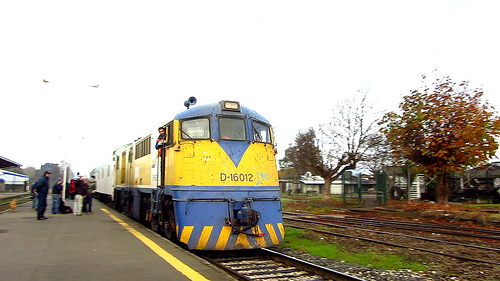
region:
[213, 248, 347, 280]
train tracks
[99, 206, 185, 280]
a yellow warning strip on a train platform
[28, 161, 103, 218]
people standing on a train platform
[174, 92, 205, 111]
a horn on a train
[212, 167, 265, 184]
identification numbers on a train engine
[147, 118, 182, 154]
a man leaning out the window of a train engine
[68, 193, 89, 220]
white pants worn by a man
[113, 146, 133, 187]
a door to a train car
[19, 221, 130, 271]
a cement platform at a train station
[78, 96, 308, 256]
a train parked at a train station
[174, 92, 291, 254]
front of train is yellow and blue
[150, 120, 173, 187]
a person on door of train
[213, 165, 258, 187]
number of train is D-16012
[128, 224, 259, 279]
a yellow line on side railroad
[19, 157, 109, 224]
group of people on a platform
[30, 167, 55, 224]
person wears blue cloths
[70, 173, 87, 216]
person wears white pants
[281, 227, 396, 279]
patch of grass near railroad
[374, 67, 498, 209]
a tree with dry leaves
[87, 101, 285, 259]
large blue and yellow train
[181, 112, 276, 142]
small windshield in front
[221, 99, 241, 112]
small front light in the top of train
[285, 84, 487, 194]
autumn trees in the right side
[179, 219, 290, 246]
yellow lines of blue train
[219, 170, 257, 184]
black letters in the front of train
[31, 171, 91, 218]
people standing on platform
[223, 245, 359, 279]
black rusty train tracks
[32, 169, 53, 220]
man wearing blue jacket on platform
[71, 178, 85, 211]
man wearing white pants standing on the platform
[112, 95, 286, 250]
blue and yellow train locomotive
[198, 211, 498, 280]
sets of train tracks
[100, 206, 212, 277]
yellow caution stripe painted on platform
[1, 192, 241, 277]
train station platform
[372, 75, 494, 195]
tree with leaves turning yellow and red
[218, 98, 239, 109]
train headlight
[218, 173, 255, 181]
locomotive identifying number D-16012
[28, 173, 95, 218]
people waiting on open air train platform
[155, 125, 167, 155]
train engineer in orange vest leaning out engine side window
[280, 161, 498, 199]
houses near the train tracks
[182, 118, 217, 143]
window of a train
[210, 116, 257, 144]
window of a train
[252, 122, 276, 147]
window of a train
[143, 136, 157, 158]
window of a train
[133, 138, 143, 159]
window of a train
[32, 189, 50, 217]
leg of a person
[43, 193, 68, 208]
leg of a person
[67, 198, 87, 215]
leg of a person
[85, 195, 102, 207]
leg of a person